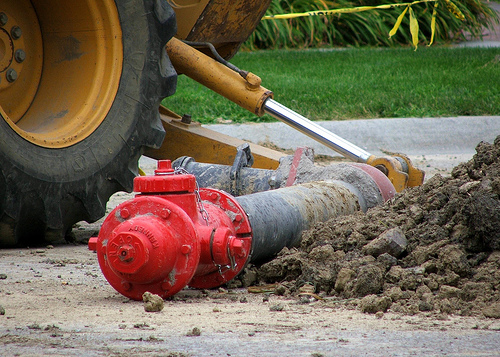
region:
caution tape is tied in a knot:
[262, 1, 468, 38]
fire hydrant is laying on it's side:
[88, 156, 403, 303]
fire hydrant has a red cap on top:
[85, 151, 410, 299]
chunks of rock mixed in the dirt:
[300, 214, 499, 321]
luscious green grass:
[285, 55, 492, 111]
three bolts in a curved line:
[4, 11, 36, 93]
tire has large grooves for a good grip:
[125, 5, 175, 159]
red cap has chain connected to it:
[133, 173, 250, 290]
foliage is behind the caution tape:
[270, 0, 497, 46]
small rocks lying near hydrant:
[80, 205, 267, 314]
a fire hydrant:
[85, 155, 254, 300]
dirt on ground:
[138, 132, 498, 335]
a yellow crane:
[3, 2, 423, 253]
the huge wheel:
[2, 7, 180, 252]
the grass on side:
[159, 47, 499, 121]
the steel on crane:
[265, 95, 370, 160]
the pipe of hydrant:
[173, 151, 395, 270]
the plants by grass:
[245, 0, 499, 43]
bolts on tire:
[0, 9, 28, 88]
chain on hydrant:
[153, 156, 238, 278]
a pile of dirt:
[310, 137, 485, 318]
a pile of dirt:
[228, 90, 495, 332]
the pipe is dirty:
[190, 137, 381, 265]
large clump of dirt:
[359, 223, 411, 256]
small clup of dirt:
[142, 288, 163, 311]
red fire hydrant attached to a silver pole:
[83, 154, 277, 313]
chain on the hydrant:
[168, 154, 214, 219]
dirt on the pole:
[290, 177, 380, 229]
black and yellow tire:
[0, 0, 191, 257]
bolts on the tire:
[1, 12, 36, 94]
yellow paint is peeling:
[19, 106, 74, 136]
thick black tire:
[0, 0, 200, 249]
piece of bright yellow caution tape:
[264, 0, 422, 21]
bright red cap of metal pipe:
[88, 157, 258, 298]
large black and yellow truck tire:
[0, 0, 180, 245]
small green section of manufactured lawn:
[307, 47, 497, 117]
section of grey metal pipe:
[251, 147, 386, 257]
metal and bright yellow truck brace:
[168, 36, 419, 189]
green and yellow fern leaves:
[258, 0, 492, 51]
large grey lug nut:
[13, 46, 28, 64]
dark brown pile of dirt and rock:
[256, 131, 496, 317]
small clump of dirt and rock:
[142, 288, 169, 313]